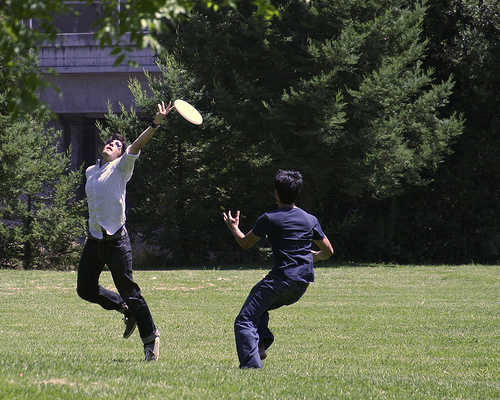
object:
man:
[67, 104, 165, 361]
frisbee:
[171, 96, 205, 128]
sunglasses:
[102, 135, 126, 149]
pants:
[70, 225, 162, 342]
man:
[219, 162, 336, 373]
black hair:
[273, 168, 304, 209]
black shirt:
[247, 205, 325, 285]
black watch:
[147, 117, 161, 131]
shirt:
[78, 146, 141, 238]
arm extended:
[126, 98, 176, 171]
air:
[175, 58, 229, 96]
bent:
[66, 274, 108, 305]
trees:
[187, 7, 426, 118]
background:
[425, 9, 488, 137]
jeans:
[233, 264, 310, 357]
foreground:
[197, 267, 240, 293]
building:
[6, 0, 186, 134]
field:
[171, 247, 231, 380]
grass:
[352, 265, 397, 363]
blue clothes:
[257, 202, 293, 360]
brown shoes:
[114, 305, 162, 362]